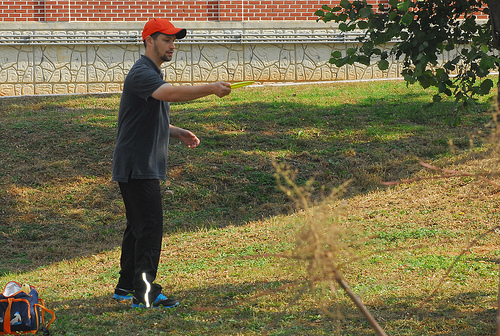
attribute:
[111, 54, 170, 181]
shirt — grey polo 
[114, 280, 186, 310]
shoes — blue , black 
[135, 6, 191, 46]
hat — orange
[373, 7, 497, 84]
leaves — tree 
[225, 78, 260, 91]
frisbee — round yellow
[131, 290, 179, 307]
shoe — black , blue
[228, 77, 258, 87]
frisbee — yellow 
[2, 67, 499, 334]
grass — green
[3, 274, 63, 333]
bag — blue, orange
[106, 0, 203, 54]
hat — orange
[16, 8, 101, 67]
wall — brick, stone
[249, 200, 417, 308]
limb — dead 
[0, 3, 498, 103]
building — brick  , red brick , side  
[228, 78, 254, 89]
frisbee — yellow 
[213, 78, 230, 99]
hand — man's 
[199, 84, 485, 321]
field — grassy 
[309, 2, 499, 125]
leaves — green 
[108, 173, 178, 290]
pants — black 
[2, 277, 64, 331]
bag — orange , blue , carry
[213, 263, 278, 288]
dirt — patches 